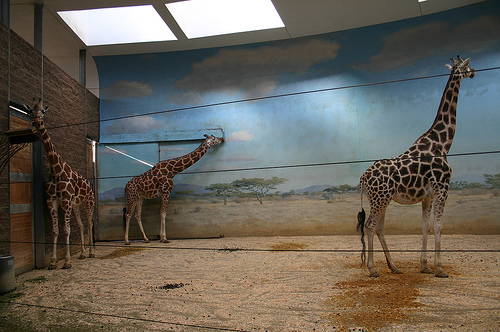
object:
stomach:
[386, 180, 422, 207]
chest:
[38, 149, 70, 210]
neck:
[166, 144, 209, 178]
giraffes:
[20, 55, 478, 278]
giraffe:
[121, 127, 226, 246]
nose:
[215, 133, 227, 147]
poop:
[157, 275, 189, 295]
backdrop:
[97, 1, 500, 238]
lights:
[54, 0, 290, 49]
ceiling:
[42, 0, 484, 56]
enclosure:
[0, 0, 500, 174]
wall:
[0, 29, 101, 270]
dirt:
[0, 233, 500, 331]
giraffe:
[22, 90, 96, 271]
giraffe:
[354, 54, 478, 278]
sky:
[95, 0, 500, 190]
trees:
[205, 174, 287, 207]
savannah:
[95, 163, 500, 241]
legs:
[418, 186, 452, 278]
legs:
[361, 167, 404, 279]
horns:
[447, 54, 480, 78]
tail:
[354, 172, 369, 268]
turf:
[324, 172, 389, 234]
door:
[6, 107, 44, 277]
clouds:
[166, 35, 343, 104]